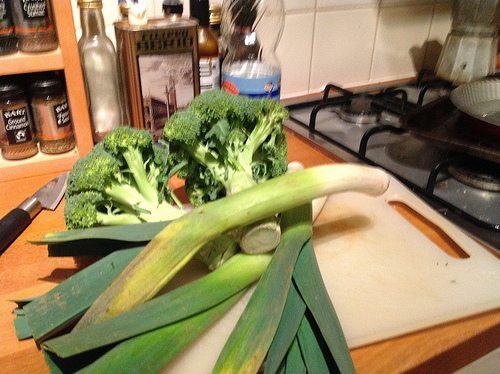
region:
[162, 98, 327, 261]
a large head of broccoli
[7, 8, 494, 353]
vegetables in a kitchen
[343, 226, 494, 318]
a white plastic cutting board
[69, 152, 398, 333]
a large leek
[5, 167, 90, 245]
a very sharp knife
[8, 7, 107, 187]
a wooden spice rack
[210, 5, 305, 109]
a bottle of vegetable oil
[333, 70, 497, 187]
a gas range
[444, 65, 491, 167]
a pie pan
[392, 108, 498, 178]
a metal cookie sheet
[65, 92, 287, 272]
two heads of broccoli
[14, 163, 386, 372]
two leeks on a cutting board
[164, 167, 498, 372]
white plastic cutting board on counter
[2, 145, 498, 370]
brown wood counter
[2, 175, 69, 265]
knife with a black handle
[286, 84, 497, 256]
gas range top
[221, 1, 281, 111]
empty, clear plastic bottle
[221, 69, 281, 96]
blue label on plastic bottle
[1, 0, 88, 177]
spices on a spice rack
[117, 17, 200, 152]
olive oil in a gold can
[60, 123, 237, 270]
A head of brocoli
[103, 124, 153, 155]
A brocoli florret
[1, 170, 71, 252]
A sharp kitchen knife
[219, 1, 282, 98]
A bottle of cooking oil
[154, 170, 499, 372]
A white plastic cutting board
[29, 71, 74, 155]
A plastic seasoning bottle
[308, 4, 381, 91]
A white kitchen tile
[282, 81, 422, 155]
A black gas burner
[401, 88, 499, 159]
A metal cookie sheet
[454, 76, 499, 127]
A metal pie pan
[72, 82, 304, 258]
two pieces of broccolis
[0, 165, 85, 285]
a knife on the counter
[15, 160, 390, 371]
leeks on cutting board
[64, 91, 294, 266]
broccoli on cutting board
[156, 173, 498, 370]
white cutting board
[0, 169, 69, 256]
silver knife with black handle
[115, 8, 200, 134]
rectangular gold can of oil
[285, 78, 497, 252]
stove top burners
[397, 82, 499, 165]
metal cookie sheet sitting on stove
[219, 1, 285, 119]
clear plastic bottle near stove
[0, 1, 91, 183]
wooden shelves for spice jars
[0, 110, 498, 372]
wooden counter top